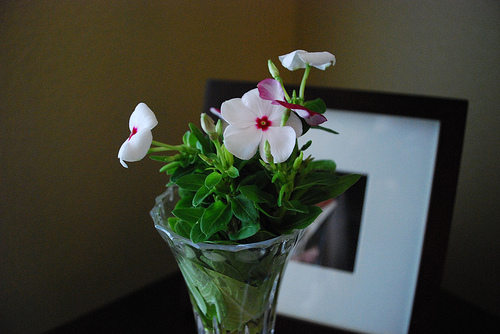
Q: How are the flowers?
A: Fresh.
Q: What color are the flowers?
A: White.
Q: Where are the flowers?
A: In a vase.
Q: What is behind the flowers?
A: A photograph.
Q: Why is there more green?
A: Stems and leaves.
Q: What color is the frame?
A: Black.